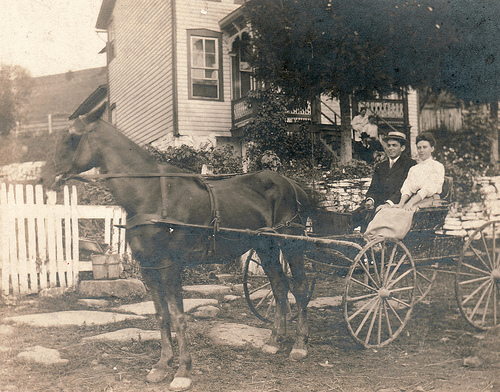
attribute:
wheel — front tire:
[334, 235, 421, 352]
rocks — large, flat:
[3, 295, 141, 369]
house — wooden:
[97, 2, 257, 152]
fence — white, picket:
[1, 179, 128, 299]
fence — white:
[13, 141, 95, 315]